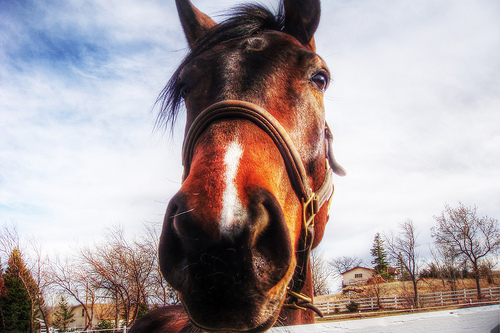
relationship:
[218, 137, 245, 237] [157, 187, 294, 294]
patch on nose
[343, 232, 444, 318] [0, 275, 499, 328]
house on hill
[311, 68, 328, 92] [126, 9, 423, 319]
eye on horse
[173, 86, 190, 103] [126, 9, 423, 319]
eye on horse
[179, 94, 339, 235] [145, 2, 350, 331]
gear on face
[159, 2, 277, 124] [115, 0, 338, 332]
hair on horse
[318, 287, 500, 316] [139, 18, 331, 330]
fence ny horse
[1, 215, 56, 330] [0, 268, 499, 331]
trees in pasture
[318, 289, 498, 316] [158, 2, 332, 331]
fence by horse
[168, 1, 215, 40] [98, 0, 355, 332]
ear on horse's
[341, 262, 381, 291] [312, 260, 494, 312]
house on hill